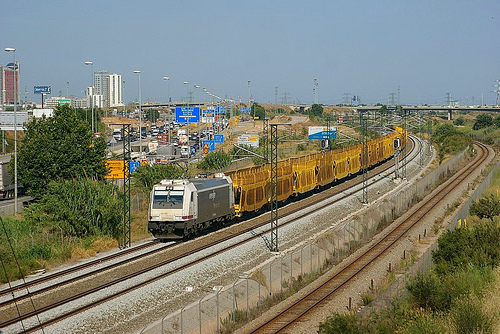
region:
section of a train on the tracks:
[139, 167, 235, 244]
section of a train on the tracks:
[222, 159, 272, 218]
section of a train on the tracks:
[264, 153, 299, 205]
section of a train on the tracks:
[290, 148, 326, 201]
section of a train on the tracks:
[312, 145, 342, 191]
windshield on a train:
[152, 188, 187, 213]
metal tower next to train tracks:
[260, 115, 285, 261]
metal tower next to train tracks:
[116, 118, 135, 250]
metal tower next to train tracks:
[355, 113, 372, 207]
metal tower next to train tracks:
[260, 115, 272, 165]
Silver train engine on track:
[150, 173, 238, 238]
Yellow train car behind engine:
[235, 158, 302, 210]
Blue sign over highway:
[174, 105, 201, 125]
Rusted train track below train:
[247, 295, 326, 331]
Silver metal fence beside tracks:
[125, 279, 268, 332]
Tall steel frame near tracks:
[265, 119, 285, 251]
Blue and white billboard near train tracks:
[310, 124, 339, 136]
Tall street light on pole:
[3, 45, 18, 219]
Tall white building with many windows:
[90, 70, 121, 106]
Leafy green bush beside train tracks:
[407, 268, 474, 308]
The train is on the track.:
[136, 154, 386, 205]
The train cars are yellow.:
[236, 148, 384, 187]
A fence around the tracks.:
[258, 203, 400, 263]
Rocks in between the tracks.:
[157, 250, 214, 274]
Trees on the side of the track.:
[403, 230, 487, 322]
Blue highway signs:
[164, 98, 206, 131]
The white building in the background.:
[84, 68, 129, 123]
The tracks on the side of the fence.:
[288, 277, 336, 316]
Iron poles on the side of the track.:
[111, 113, 148, 254]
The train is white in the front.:
[151, 176, 198, 228]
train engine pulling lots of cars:
[148, 175, 233, 240]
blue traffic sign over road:
[175, 104, 202, 122]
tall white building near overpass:
[93, 70, 120, 104]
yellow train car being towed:
[225, 157, 295, 211]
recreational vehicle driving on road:
[178, 145, 193, 155]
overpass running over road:
[132, 100, 212, 112]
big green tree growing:
[9, 102, 110, 199]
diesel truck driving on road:
[156, 144, 178, 161]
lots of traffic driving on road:
[110, 122, 222, 166]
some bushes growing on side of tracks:
[431, 121, 470, 153]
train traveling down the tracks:
[148, 106, 415, 238]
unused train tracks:
[214, 121, 496, 317]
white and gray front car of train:
[136, 168, 231, 231]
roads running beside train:
[5, 101, 242, 229]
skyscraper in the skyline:
[85, 67, 123, 110]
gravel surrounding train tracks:
[6, 119, 436, 332]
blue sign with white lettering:
[171, 99, 195, 122]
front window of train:
[147, 194, 187, 213]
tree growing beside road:
[11, 103, 99, 190]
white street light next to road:
[4, 44, 22, 214]